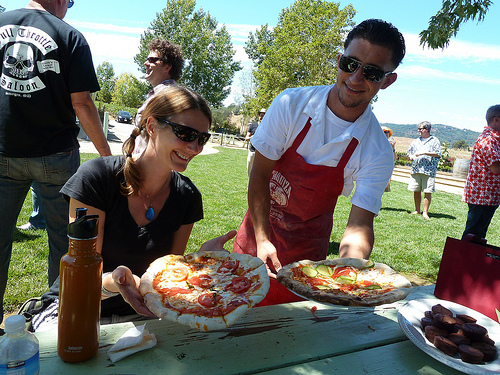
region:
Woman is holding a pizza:
[60, 83, 270, 334]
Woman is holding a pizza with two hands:
[65, 81, 273, 337]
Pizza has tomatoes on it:
[142, 246, 274, 328]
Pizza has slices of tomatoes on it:
[136, 247, 269, 331]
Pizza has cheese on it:
[133, 247, 271, 328]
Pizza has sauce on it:
[136, 245, 271, 330]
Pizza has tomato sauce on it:
[135, 247, 272, 333]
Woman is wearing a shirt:
[56, 152, 203, 317]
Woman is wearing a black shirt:
[58, 150, 207, 312]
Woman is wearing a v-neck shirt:
[58, 152, 206, 319]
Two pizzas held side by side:
[138, 245, 409, 320]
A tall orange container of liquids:
[57, 207, 104, 362]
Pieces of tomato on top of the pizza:
[193, 274, 248, 308]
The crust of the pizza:
[184, 312, 241, 332]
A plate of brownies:
[402, 295, 498, 372]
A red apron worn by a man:
[242, 118, 356, 298]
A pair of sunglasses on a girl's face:
[162, 117, 217, 147]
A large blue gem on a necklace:
[142, 205, 157, 220]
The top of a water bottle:
[0, 312, 45, 372]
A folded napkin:
[106, 322, 158, 364]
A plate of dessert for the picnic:
[398, 295, 499, 373]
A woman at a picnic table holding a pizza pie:
[58, 81, 275, 338]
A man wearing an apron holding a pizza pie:
[227, 17, 423, 309]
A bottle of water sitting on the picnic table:
[2, 313, 45, 373]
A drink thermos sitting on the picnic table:
[54, 204, 107, 366]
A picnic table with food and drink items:
[0, 288, 497, 373]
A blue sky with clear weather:
[1, 0, 498, 127]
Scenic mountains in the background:
[378, 117, 499, 144]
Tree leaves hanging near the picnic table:
[413, 0, 498, 55]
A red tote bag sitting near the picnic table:
[435, 232, 499, 324]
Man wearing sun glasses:
[333, 15, 409, 111]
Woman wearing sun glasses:
[121, 80, 213, 198]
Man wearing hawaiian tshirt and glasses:
[407, 120, 443, 220]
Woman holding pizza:
[55, 81, 267, 341]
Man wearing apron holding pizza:
[232, 16, 411, 329]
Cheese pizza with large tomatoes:
[137, 246, 270, 332]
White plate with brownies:
[397, 295, 498, 372]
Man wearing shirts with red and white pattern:
[457, 98, 499, 250]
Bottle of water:
[0, 310, 45, 374]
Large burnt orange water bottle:
[54, 203, 103, 367]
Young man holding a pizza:
[269, 18, 410, 308]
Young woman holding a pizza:
[100, 88, 269, 332]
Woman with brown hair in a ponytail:
[121, 85, 212, 197]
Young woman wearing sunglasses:
[144, 87, 213, 173]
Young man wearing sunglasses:
[336, 18, 405, 107]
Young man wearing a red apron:
[238, 17, 404, 254]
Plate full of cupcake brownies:
[399, 298, 499, 374]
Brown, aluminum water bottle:
[57, 205, 100, 362]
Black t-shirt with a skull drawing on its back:
[0, 9, 98, 157]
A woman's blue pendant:
[145, 206, 154, 218]